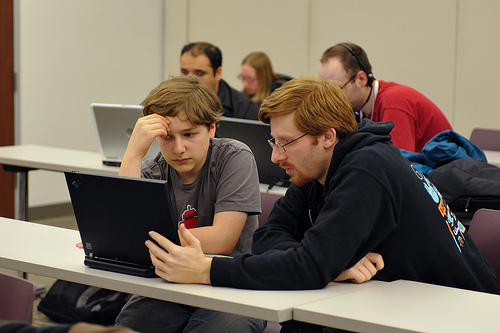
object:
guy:
[147, 77, 498, 301]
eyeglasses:
[262, 127, 312, 154]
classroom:
[18, 8, 497, 328]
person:
[117, 72, 264, 331]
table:
[3, 137, 299, 203]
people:
[206, 73, 499, 331]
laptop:
[85, 92, 197, 178]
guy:
[311, 36, 473, 168]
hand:
[138, 218, 215, 284]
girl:
[238, 54, 284, 114]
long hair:
[241, 54, 274, 90]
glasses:
[239, 69, 256, 83]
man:
[141, 76, 498, 331]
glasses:
[259, 128, 312, 152]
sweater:
[371, 78, 456, 153]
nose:
[168, 137, 190, 159]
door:
[2, 3, 17, 213]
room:
[3, 2, 494, 332]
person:
[239, 49, 284, 102]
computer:
[62, 162, 188, 282]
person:
[154, 44, 284, 159]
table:
[459, 127, 499, 165]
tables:
[2, 215, 498, 332]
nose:
[266, 146, 289, 164]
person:
[144, 92, 464, 295]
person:
[321, 46, 457, 155]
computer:
[210, 108, 293, 184]